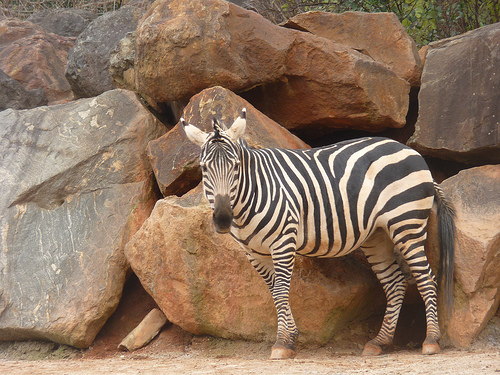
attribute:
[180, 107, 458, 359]
zebra — looking at camera, white, black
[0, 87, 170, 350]
rock — big, gray, hard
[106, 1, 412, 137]
rock — hard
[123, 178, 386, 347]
rock — hard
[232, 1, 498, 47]
trees — seen from background